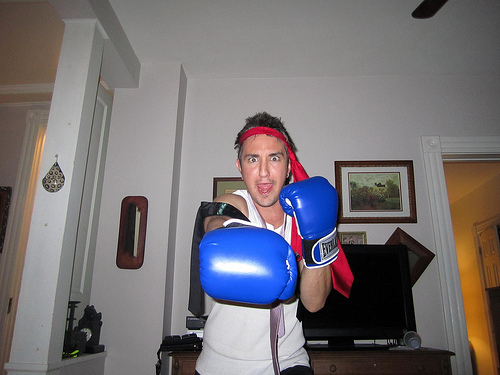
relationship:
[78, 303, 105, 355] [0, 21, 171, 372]
clock hidden in corner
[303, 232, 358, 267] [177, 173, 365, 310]
writing on gloves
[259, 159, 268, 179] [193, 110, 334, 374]
nose on man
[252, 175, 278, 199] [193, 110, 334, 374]
mouth on man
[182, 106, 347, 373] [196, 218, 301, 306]
man wearing boxing gear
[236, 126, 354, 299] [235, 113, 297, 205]
red tie around head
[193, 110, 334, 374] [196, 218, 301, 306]
man holding boxing gear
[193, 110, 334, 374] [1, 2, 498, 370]
man in room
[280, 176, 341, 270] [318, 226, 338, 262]
boxing gear with label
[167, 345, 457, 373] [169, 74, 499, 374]
table by wall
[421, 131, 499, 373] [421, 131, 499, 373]
doorway with doorway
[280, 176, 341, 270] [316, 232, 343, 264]
boxing gear with letters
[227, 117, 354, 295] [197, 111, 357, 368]
red tie on man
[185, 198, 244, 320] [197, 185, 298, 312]
tie on arm